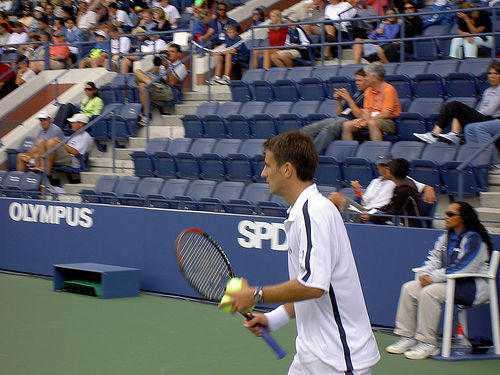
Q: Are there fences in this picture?
A: No, there are no fences.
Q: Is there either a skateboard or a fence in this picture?
A: No, there are no fences or skateboards.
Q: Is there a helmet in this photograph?
A: No, there are no helmets.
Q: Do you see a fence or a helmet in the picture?
A: No, there are no helmets or fences.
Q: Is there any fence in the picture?
A: No, there are no fences.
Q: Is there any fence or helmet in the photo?
A: No, there are no fences or helmets.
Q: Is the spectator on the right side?
A: Yes, the spectator is on the right of the image.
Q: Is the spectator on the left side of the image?
A: No, the spectator is on the right of the image.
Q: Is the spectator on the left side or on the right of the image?
A: The spectator is on the right of the image.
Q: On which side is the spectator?
A: The spectator is on the right of the image.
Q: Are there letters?
A: Yes, there are letters.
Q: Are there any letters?
A: Yes, there are letters.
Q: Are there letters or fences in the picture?
A: Yes, there are letters.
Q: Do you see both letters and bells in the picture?
A: No, there are letters but no bells.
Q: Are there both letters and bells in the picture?
A: No, there are letters but no bells.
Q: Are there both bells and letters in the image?
A: No, there are letters but no bells.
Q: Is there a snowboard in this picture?
A: No, there are no snowboards.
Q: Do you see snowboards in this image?
A: No, there are no snowboards.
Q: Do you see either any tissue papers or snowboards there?
A: No, there are no snowboards or tissue papers.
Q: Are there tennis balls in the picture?
A: Yes, there are tennis balls.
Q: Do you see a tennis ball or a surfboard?
A: Yes, there are tennis balls.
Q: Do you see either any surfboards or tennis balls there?
A: Yes, there are tennis balls.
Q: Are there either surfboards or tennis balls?
A: Yes, there are tennis balls.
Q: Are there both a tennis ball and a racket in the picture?
A: Yes, there are both a tennis ball and a racket.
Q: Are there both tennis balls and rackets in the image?
A: Yes, there are both tennis balls and a racket.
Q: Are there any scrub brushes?
A: No, there are no scrub brushes.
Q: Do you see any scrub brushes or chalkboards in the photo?
A: No, there are no scrub brushes or chalkboards.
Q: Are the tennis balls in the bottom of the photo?
A: Yes, the tennis balls are in the bottom of the image.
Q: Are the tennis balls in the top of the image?
A: No, the tennis balls are in the bottom of the image.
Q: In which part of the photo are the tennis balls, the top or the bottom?
A: The tennis balls are in the bottom of the image.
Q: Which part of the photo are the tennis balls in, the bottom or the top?
A: The tennis balls are in the bottom of the image.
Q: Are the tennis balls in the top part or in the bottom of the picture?
A: The tennis balls are in the bottom of the image.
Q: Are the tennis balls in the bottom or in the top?
A: The tennis balls are in the bottom of the image.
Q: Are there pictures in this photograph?
A: No, there are no pictures.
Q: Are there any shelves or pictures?
A: No, there are no pictures or shelves.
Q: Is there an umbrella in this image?
A: No, there are no umbrellas.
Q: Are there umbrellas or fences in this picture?
A: No, there are no umbrellas or fences.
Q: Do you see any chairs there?
A: Yes, there is a chair.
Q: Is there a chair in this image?
A: Yes, there is a chair.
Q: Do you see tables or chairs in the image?
A: Yes, there is a chair.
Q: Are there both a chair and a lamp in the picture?
A: No, there is a chair but no lamps.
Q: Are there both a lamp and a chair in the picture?
A: No, there is a chair but no lamps.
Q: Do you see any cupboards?
A: No, there are no cupboards.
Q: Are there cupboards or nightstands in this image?
A: No, there are no cupboards or nightstands.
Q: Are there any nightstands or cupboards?
A: No, there are no cupboards or nightstands.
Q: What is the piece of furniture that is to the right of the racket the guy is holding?
A: The piece of furniture is a chair.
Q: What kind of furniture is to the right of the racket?
A: The piece of furniture is a chair.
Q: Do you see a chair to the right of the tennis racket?
A: Yes, there is a chair to the right of the tennis racket.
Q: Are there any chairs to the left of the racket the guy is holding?
A: No, the chair is to the right of the tennis racket.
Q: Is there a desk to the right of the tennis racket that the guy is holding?
A: No, there is a chair to the right of the tennis racket.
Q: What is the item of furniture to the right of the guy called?
A: The piece of furniture is a chair.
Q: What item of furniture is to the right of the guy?
A: The piece of furniture is a chair.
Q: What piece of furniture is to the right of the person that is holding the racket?
A: The piece of furniture is a chair.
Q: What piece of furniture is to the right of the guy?
A: The piece of furniture is a chair.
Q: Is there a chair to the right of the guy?
A: Yes, there is a chair to the right of the guy.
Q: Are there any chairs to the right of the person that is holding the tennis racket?
A: Yes, there is a chair to the right of the guy.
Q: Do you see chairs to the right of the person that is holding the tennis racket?
A: Yes, there is a chair to the right of the guy.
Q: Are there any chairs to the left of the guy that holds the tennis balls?
A: No, the chair is to the right of the guy.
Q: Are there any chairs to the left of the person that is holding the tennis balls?
A: No, the chair is to the right of the guy.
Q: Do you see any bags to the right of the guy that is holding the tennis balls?
A: No, there is a chair to the right of the guy.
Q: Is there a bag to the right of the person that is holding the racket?
A: No, there is a chair to the right of the guy.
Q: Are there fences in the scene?
A: No, there are no fences.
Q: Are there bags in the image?
A: No, there are no bags.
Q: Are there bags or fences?
A: No, there are no bags or fences.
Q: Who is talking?
A: The people are talking.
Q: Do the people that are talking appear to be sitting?
A: Yes, the people are sitting.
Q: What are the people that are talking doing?
A: The people are sitting.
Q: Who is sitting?
A: The people are sitting.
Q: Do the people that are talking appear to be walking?
A: No, the people are sitting.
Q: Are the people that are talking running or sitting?
A: The people are sitting.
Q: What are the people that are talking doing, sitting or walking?
A: The people are sitting.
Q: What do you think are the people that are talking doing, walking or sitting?
A: The people are sitting.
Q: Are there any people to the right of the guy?
A: Yes, there are people to the right of the guy.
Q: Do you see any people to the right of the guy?
A: Yes, there are people to the right of the guy.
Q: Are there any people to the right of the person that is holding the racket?
A: Yes, there are people to the right of the guy.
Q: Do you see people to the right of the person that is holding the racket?
A: Yes, there are people to the right of the guy.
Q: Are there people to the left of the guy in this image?
A: No, the people are to the right of the guy.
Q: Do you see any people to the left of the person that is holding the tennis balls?
A: No, the people are to the right of the guy.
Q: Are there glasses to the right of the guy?
A: No, there are people to the right of the guy.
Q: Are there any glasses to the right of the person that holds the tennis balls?
A: No, there are people to the right of the guy.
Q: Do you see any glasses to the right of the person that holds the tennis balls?
A: No, there are people to the right of the guy.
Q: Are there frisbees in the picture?
A: No, there are no frisbees.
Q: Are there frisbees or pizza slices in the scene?
A: No, there are no frisbees or pizza slices.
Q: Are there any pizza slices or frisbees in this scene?
A: No, there are no frisbees or pizza slices.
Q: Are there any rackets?
A: Yes, there is a racket.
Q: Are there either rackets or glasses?
A: Yes, there is a racket.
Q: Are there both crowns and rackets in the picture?
A: No, there is a racket but no crowns.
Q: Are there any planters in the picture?
A: No, there are no planters.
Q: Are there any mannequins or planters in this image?
A: No, there are no planters or mannequins.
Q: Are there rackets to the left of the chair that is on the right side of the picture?
A: Yes, there is a racket to the left of the chair.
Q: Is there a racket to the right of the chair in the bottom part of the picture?
A: No, the racket is to the left of the chair.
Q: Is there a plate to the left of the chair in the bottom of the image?
A: No, there is a racket to the left of the chair.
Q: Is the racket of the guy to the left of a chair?
A: Yes, the tennis racket is to the left of a chair.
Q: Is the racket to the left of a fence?
A: No, the racket is to the left of a chair.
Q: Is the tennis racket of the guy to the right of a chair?
A: No, the racket is to the left of a chair.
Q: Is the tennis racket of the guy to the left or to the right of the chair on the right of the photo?
A: The racket is to the left of the chair.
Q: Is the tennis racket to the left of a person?
A: Yes, the tennis racket is to the left of a person.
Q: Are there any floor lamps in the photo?
A: No, there are no floor lamps.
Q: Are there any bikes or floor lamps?
A: No, there are no floor lamps or bikes.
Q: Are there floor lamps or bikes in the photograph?
A: No, there are no floor lamps or bikes.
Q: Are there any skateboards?
A: No, there are no skateboards.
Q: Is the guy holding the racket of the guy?
A: Yes, the guy is holding the tennis racket.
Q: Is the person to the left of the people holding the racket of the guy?
A: Yes, the guy is holding the tennis racket.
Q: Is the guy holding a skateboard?
A: No, the guy is holding the tennis racket.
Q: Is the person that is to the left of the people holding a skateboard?
A: No, the guy is holding the tennis racket.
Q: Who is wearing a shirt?
A: The guy is wearing a shirt.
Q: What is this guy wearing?
A: The guy is wearing a shirt.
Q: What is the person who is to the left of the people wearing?
A: The guy is wearing a shirt.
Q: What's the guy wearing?
A: The guy is wearing a shirt.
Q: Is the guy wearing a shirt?
A: Yes, the guy is wearing a shirt.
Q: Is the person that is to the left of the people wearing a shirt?
A: Yes, the guy is wearing a shirt.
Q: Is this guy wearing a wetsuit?
A: No, the guy is wearing a shirt.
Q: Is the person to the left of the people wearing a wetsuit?
A: No, the guy is wearing a shirt.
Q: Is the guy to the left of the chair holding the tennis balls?
A: Yes, the guy is holding the tennis balls.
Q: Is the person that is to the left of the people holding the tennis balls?
A: Yes, the guy is holding the tennis balls.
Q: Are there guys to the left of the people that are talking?
A: Yes, there is a guy to the left of the people.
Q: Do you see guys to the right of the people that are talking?
A: No, the guy is to the left of the people.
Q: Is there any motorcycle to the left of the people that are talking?
A: No, there is a guy to the left of the people.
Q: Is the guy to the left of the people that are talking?
A: Yes, the guy is to the left of the people.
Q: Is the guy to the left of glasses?
A: No, the guy is to the left of the people.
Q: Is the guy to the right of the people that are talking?
A: No, the guy is to the left of the people.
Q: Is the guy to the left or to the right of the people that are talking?
A: The guy is to the left of the people.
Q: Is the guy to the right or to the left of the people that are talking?
A: The guy is to the left of the people.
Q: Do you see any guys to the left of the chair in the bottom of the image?
A: Yes, there is a guy to the left of the chair.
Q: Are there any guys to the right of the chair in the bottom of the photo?
A: No, the guy is to the left of the chair.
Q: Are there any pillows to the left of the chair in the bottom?
A: No, there is a guy to the left of the chair.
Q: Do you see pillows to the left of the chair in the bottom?
A: No, there is a guy to the left of the chair.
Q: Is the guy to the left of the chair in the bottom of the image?
A: Yes, the guy is to the left of the chair.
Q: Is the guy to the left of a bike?
A: No, the guy is to the left of the chair.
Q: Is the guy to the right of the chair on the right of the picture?
A: No, the guy is to the left of the chair.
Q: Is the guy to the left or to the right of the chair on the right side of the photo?
A: The guy is to the left of the chair.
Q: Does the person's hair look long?
A: Yes, the hair is long.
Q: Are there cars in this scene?
A: No, there are no cars.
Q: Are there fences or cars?
A: No, there are no cars or fences.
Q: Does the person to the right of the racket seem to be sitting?
A: Yes, the person is sitting.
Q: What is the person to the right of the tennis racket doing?
A: The person is sitting.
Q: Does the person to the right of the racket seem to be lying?
A: No, the person is sitting.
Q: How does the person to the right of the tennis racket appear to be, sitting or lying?
A: The person is sitting.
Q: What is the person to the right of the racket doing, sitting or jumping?
A: The person is sitting.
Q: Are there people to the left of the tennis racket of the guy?
A: No, the person is to the right of the tennis racket.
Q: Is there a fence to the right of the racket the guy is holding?
A: No, there is a person to the right of the tennis racket.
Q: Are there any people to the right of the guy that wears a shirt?
A: Yes, there is a person to the right of the guy.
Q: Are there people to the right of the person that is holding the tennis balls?
A: Yes, there is a person to the right of the guy.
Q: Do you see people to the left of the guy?
A: No, the person is to the right of the guy.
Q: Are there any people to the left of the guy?
A: No, the person is to the right of the guy.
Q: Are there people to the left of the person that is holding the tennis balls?
A: No, the person is to the right of the guy.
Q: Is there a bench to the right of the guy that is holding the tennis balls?
A: No, there is a person to the right of the guy.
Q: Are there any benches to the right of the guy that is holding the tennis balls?
A: No, there is a person to the right of the guy.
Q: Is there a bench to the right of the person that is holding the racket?
A: No, there is a person to the right of the guy.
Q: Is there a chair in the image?
A: Yes, there is a chair.